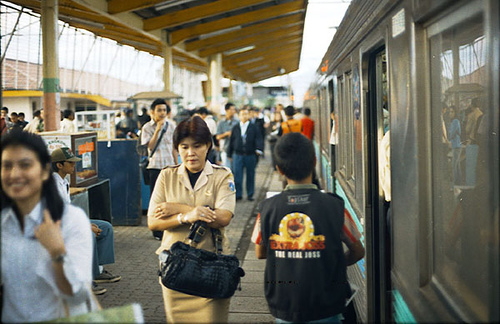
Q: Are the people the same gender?
A: No, they are both male and female.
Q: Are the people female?
A: No, they are both male and female.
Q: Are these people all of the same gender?
A: No, they are both male and female.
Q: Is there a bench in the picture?
A: No, there are no benches.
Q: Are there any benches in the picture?
A: No, there are no benches.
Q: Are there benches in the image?
A: No, there are no benches.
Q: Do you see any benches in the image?
A: No, there are no benches.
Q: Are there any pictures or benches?
A: No, there are no benches or pictures.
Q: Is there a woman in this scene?
A: Yes, there is a woman.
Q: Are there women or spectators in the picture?
A: Yes, there is a woman.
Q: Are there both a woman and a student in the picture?
A: No, there is a woman but no students.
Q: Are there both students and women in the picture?
A: No, there is a woman but no students.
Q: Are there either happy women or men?
A: Yes, there is a happy woman.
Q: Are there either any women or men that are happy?
A: Yes, the woman is happy.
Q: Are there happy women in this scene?
A: Yes, there is a happy woman.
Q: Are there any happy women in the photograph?
A: Yes, there is a happy woman.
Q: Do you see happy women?
A: Yes, there is a happy woman.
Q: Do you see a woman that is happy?
A: Yes, there is a woman that is happy.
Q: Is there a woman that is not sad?
A: Yes, there is a happy woman.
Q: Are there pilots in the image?
A: No, there are no pilots.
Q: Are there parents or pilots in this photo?
A: No, there are no pilots or parents.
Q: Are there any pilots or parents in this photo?
A: No, there are no pilots or parents.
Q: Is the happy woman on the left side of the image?
A: Yes, the woman is on the left of the image.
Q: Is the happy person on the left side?
A: Yes, the woman is on the left of the image.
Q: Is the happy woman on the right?
A: No, the woman is on the left of the image.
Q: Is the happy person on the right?
A: No, the woman is on the left of the image.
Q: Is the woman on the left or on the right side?
A: The woman is on the left of the image.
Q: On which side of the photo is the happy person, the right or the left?
A: The woman is on the left of the image.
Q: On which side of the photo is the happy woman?
A: The woman is on the left of the image.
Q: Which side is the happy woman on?
A: The woman is on the left of the image.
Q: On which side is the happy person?
A: The woman is on the left of the image.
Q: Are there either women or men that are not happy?
A: No, there is a woman but she is happy.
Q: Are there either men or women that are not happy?
A: No, there is a woman but she is happy.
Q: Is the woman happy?
A: Yes, the woman is happy.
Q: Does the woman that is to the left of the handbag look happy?
A: Yes, the woman is happy.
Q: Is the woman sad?
A: No, the woman is happy.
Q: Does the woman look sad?
A: No, the woman is happy.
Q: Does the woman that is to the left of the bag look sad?
A: No, the woman is happy.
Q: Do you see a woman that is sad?
A: No, there is a woman but she is happy.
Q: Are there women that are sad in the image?
A: No, there is a woman but she is happy.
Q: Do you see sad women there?
A: No, there is a woman but she is happy.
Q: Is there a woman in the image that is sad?
A: No, there is a woman but she is happy.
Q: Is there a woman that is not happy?
A: No, there is a woman but she is happy.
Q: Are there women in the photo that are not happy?
A: No, there is a woman but she is happy.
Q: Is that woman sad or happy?
A: The woman is happy.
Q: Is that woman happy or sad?
A: The woman is happy.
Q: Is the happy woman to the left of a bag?
A: Yes, the woman is to the left of a bag.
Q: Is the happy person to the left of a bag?
A: Yes, the woman is to the left of a bag.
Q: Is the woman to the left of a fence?
A: No, the woman is to the left of a bag.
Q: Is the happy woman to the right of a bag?
A: No, the woman is to the left of a bag.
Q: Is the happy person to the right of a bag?
A: No, the woman is to the left of a bag.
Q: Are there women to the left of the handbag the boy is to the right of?
A: Yes, there is a woman to the left of the handbag.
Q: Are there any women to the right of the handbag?
A: No, the woman is to the left of the handbag.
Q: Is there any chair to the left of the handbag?
A: No, there is a woman to the left of the handbag.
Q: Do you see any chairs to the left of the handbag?
A: No, there is a woman to the left of the handbag.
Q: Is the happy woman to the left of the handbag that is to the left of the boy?
A: Yes, the woman is to the left of the handbag.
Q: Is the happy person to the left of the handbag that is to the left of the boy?
A: Yes, the woman is to the left of the handbag.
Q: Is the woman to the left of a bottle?
A: No, the woman is to the left of the handbag.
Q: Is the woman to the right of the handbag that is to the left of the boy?
A: No, the woman is to the left of the handbag.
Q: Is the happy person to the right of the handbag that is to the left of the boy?
A: No, the woman is to the left of the handbag.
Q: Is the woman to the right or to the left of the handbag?
A: The woman is to the left of the handbag.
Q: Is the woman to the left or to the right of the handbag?
A: The woman is to the left of the handbag.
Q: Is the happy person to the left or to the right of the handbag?
A: The woman is to the left of the handbag.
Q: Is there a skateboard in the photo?
A: No, there are no skateboards.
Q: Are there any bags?
A: Yes, there is a bag.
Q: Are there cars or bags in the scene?
A: Yes, there is a bag.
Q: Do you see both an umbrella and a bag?
A: No, there is a bag but no umbrellas.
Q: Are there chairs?
A: No, there are no chairs.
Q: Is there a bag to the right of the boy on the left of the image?
A: Yes, there is a bag to the right of the boy.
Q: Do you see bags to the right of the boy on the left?
A: Yes, there is a bag to the right of the boy.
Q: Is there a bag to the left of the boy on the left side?
A: No, the bag is to the right of the boy.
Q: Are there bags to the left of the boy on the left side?
A: No, the bag is to the right of the boy.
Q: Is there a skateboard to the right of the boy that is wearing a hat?
A: No, there is a bag to the right of the boy.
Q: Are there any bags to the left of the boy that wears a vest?
A: Yes, there is a bag to the left of the boy.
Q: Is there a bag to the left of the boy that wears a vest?
A: Yes, there is a bag to the left of the boy.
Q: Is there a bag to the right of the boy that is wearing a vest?
A: No, the bag is to the left of the boy.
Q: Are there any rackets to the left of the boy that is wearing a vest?
A: No, there is a bag to the left of the boy.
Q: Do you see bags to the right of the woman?
A: Yes, there is a bag to the right of the woman.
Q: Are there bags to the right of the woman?
A: Yes, there is a bag to the right of the woman.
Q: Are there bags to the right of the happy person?
A: Yes, there is a bag to the right of the woman.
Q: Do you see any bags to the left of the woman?
A: No, the bag is to the right of the woman.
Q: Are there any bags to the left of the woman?
A: No, the bag is to the right of the woman.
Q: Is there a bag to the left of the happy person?
A: No, the bag is to the right of the woman.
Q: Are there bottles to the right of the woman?
A: No, there is a bag to the right of the woman.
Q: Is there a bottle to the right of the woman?
A: No, there is a bag to the right of the woman.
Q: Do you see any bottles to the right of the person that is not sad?
A: No, there is a bag to the right of the woman.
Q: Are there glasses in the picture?
A: No, there are no glasses.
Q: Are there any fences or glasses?
A: No, there are no glasses or fences.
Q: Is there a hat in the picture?
A: Yes, there is a hat.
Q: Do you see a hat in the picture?
A: Yes, there is a hat.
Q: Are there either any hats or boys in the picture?
A: Yes, there is a hat.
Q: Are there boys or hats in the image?
A: Yes, there is a hat.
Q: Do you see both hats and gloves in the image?
A: No, there is a hat but no gloves.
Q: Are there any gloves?
A: No, there are no gloves.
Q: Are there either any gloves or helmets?
A: No, there are no gloves or helmets.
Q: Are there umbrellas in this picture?
A: No, there are no umbrellas.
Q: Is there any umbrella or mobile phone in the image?
A: No, there are no umbrellas or cell phones.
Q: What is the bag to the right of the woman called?
A: The bag is a handbag.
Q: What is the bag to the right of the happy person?
A: The bag is a handbag.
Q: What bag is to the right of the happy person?
A: The bag is a handbag.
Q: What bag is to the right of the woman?
A: The bag is a handbag.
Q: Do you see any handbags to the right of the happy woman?
A: Yes, there is a handbag to the right of the woman.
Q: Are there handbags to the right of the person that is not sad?
A: Yes, there is a handbag to the right of the woman.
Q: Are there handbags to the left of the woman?
A: No, the handbag is to the right of the woman.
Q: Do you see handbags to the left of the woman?
A: No, the handbag is to the right of the woman.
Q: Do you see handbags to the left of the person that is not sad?
A: No, the handbag is to the right of the woman.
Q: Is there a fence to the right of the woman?
A: No, there is a handbag to the right of the woman.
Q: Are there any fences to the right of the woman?
A: No, there is a handbag to the right of the woman.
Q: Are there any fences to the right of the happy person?
A: No, there is a handbag to the right of the woman.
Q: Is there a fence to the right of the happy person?
A: No, there is a handbag to the right of the woman.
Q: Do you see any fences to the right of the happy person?
A: No, there is a handbag to the right of the woman.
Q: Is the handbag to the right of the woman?
A: Yes, the handbag is to the right of the woman.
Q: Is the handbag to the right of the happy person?
A: Yes, the handbag is to the right of the woman.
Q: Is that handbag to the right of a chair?
A: No, the handbag is to the right of the woman.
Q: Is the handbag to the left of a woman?
A: No, the handbag is to the right of a woman.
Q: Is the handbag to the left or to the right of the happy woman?
A: The handbag is to the right of the woman.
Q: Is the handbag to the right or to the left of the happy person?
A: The handbag is to the right of the woman.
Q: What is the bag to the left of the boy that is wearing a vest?
A: The bag is a handbag.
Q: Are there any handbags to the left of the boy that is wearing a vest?
A: Yes, there is a handbag to the left of the boy.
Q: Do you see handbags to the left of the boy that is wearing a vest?
A: Yes, there is a handbag to the left of the boy.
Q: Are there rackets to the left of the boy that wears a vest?
A: No, there is a handbag to the left of the boy.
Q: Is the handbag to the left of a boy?
A: Yes, the handbag is to the left of a boy.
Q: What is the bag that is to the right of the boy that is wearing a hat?
A: The bag is a handbag.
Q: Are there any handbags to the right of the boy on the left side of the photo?
A: Yes, there is a handbag to the right of the boy.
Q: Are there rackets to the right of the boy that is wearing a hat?
A: No, there is a handbag to the right of the boy.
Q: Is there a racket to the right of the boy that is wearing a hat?
A: No, there is a handbag to the right of the boy.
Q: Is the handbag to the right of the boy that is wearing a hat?
A: Yes, the handbag is to the right of the boy.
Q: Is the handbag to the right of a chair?
A: No, the handbag is to the right of the boy.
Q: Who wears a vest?
A: The boy wears a vest.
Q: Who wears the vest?
A: The boy wears a vest.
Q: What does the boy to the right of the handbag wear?
A: The boy wears a vest.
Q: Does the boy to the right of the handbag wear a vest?
A: Yes, the boy wears a vest.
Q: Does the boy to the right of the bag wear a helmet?
A: No, the boy wears a vest.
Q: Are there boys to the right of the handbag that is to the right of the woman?
A: Yes, there is a boy to the right of the handbag.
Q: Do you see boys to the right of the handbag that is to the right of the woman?
A: Yes, there is a boy to the right of the handbag.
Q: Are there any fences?
A: No, there are no fences.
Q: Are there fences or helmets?
A: No, there are no fences or helmets.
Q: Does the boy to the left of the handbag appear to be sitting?
A: Yes, the boy is sitting.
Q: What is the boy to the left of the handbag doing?
A: The boy is sitting.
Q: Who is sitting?
A: The boy is sitting.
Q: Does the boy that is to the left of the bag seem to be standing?
A: No, the boy is sitting.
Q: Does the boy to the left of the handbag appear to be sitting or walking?
A: The boy is sitting.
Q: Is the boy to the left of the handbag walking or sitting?
A: The boy is sitting.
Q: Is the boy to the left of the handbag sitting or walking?
A: The boy is sitting.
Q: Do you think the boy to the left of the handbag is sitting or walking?
A: The boy is sitting.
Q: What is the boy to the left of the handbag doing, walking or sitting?
A: The boy is sitting.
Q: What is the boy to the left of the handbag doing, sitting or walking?
A: The boy is sitting.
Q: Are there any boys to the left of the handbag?
A: Yes, there is a boy to the left of the handbag.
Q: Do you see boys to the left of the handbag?
A: Yes, there is a boy to the left of the handbag.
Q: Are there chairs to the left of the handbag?
A: No, there is a boy to the left of the handbag.